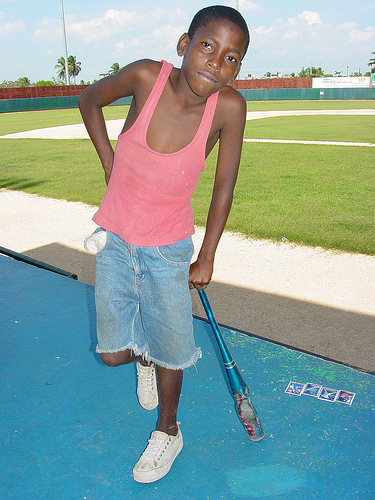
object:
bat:
[186, 274, 265, 443]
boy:
[77, 3, 250, 485]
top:
[90, 58, 219, 248]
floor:
[0, 98, 374, 499]